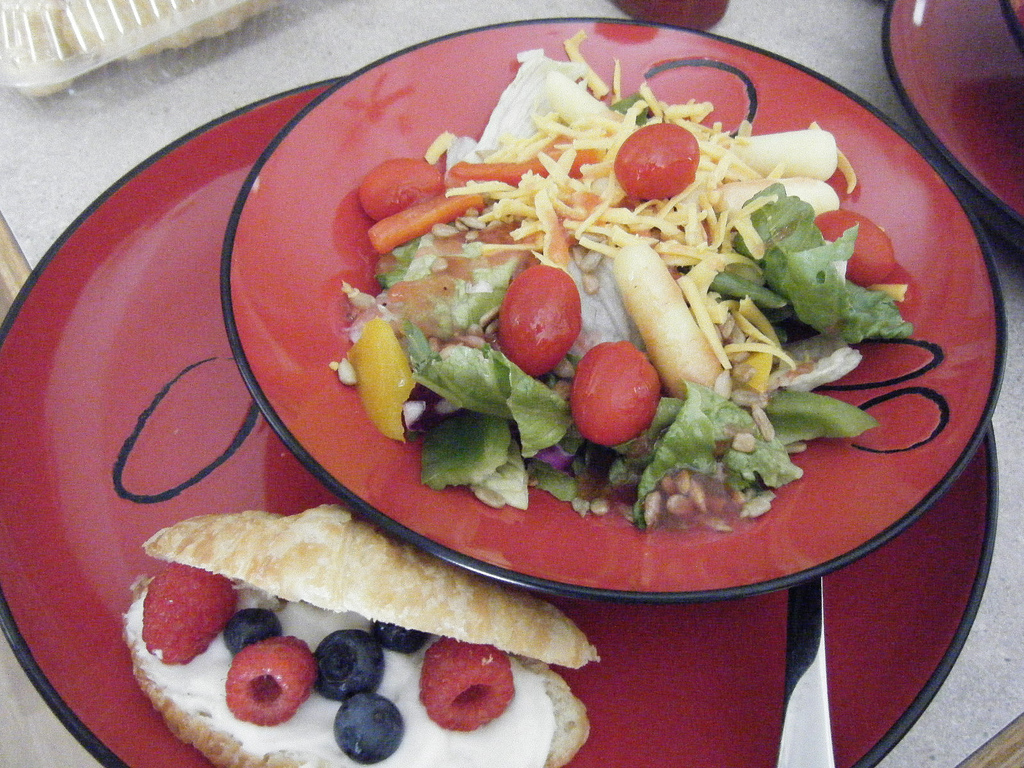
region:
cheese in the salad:
[669, 221, 720, 269]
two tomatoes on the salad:
[488, 258, 670, 464]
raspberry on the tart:
[415, 635, 515, 744]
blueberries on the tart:
[313, 635, 396, 766]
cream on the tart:
[456, 729, 543, 756]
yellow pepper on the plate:
[348, 301, 415, 457]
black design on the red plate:
[78, 361, 265, 513]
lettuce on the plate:
[437, 373, 513, 451]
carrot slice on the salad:
[368, 200, 476, 257]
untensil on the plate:
[753, 598, 858, 766]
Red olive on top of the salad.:
[578, 338, 643, 428]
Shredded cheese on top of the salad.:
[518, 154, 577, 199]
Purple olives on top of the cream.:
[315, 614, 413, 760]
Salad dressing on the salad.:
[627, 462, 758, 532]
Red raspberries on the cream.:
[431, 637, 505, 720]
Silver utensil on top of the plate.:
[778, 558, 835, 762]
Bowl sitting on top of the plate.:
[209, 11, 1007, 552]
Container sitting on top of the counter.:
[10, 8, 127, 111]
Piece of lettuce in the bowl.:
[490, 21, 611, 123]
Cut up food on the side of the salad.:
[349, 285, 433, 456]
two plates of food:
[19, 19, 971, 766]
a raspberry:
[145, 568, 237, 652]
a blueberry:
[315, 635, 399, 697]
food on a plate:
[246, 18, 1015, 588]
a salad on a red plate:
[242, 21, 960, 585]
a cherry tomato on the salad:
[622, 120, 698, 184]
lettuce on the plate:
[413, 339, 518, 498]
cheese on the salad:
[515, 121, 661, 239]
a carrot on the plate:
[376, 189, 474, 247]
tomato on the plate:
[503, 261, 580, 375]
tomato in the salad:
[566, 326, 662, 444]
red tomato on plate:
[608, 118, 710, 195]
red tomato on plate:
[813, 204, 897, 282]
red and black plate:
[204, 17, 1018, 603]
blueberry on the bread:
[330, 690, 416, 760]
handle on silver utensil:
[775, 583, 878, 762]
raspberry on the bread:
[131, 564, 240, 662]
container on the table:
[0, 0, 261, 103]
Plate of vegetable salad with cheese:
[212, 15, 1012, 610]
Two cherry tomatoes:
[498, 262, 664, 455]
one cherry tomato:
[615, 120, 702, 203]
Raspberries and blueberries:
[138, 559, 516, 766]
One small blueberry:
[334, 689, 407, 765]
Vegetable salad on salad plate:
[211, 13, 1014, 606]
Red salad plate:
[214, 10, 1012, 611]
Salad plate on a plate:
[2, 13, 1014, 766]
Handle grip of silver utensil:
[770, 591, 841, 765]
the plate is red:
[805, 474, 885, 533]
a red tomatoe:
[585, 350, 644, 439]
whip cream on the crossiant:
[413, 724, 465, 766]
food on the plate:
[366, 58, 911, 488]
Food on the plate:
[334, 86, 923, 510]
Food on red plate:
[356, 86, 897, 492]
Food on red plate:
[364, 70, 889, 492]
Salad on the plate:
[340, 88, 901, 475]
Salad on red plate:
[363, 76, 913, 514]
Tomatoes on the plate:
[503, 265, 668, 436]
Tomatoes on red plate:
[467, 249, 679, 456]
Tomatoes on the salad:
[474, 259, 680, 449]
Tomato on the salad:
[555, 323, 670, 442]